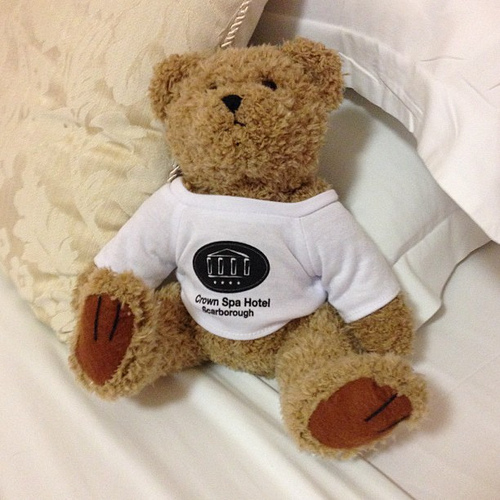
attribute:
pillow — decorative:
[275, 89, 499, 336]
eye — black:
[201, 78, 220, 93]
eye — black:
[255, 77, 282, 92]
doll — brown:
[66, 37, 433, 462]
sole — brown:
[306, 379, 407, 442]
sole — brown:
[78, 289, 134, 379]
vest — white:
[92, 175, 402, 341]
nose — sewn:
[220, 93, 242, 110]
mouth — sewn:
[220, 114, 252, 131]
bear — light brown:
[76, 29, 450, 460]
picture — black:
[187, 235, 272, 292]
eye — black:
[208, 83, 219, 89]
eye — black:
[260, 76, 281, 89]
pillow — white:
[318, 88, 493, 333]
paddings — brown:
[305, 372, 412, 459]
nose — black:
[216, 93, 245, 112]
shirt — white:
[146, 214, 325, 340]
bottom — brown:
[73, 291, 137, 387]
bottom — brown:
[305, 374, 412, 452]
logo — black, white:
[187, 241, 278, 326]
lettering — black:
[195, 293, 272, 321]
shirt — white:
[96, 181, 404, 341]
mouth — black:
[222, 119, 248, 133]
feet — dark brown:
[292, 357, 426, 465]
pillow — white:
[257, 7, 496, 322]